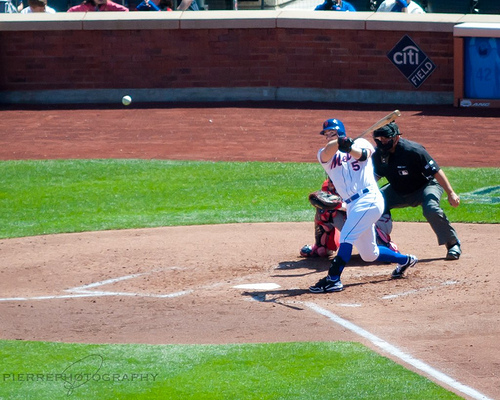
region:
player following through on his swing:
[293, 103, 422, 294]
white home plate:
[240, 280, 276, 293]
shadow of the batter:
[237, 280, 308, 313]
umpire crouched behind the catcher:
[370, 127, 465, 257]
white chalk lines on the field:
[2, 252, 482, 399]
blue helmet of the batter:
[315, 114, 342, 138]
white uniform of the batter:
[318, 148, 380, 255]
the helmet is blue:
[321, 119, 348, 132]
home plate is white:
[237, 271, 282, 310]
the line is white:
[300, 298, 450, 398]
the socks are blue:
[335, 239, 405, 277]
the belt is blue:
[344, 195, 376, 205]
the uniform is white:
[322, 137, 392, 273]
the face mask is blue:
[377, 127, 397, 156]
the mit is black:
[307, 192, 345, 217]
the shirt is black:
[379, 140, 444, 201]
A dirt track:
[105, 239, 226, 304]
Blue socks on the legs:
[335, 242, 353, 280]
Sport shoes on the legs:
[297, 252, 436, 293]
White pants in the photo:
[347, 190, 382, 252]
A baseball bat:
[360, 102, 401, 144]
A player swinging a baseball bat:
[277, 102, 419, 279]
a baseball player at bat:
[305, 109, 417, 291]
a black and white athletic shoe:
[307, 275, 342, 294]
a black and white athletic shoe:
[390, 252, 417, 277]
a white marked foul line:
[0, 291, 93, 302]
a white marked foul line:
[304, 302, 489, 399]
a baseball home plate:
[232, 280, 279, 290]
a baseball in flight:
[121, 94, 130, 104]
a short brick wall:
[0, 13, 457, 109]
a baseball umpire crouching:
[371, 122, 462, 260]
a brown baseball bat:
[349, 109, 401, 140]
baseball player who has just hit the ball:
[313, 113, 415, 292]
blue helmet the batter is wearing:
[318, 117, 347, 137]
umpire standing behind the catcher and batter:
[368, 122, 462, 265]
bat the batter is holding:
[350, 108, 403, 150]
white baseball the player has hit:
[118, 92, 134, 107]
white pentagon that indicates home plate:
[226, 275, 283, 293]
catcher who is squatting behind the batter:
[295, 173, 392, 263]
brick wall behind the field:
[2, 54, 461, 104]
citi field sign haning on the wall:
[387, 54, 434, 86]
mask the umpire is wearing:
[370, 123, 396, 153]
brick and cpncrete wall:
[1, 11, 450, 107]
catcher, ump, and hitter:
[297, 109, 462, 294]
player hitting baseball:
[308, 108, 418, 293]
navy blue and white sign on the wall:
[391, 34, 434, 85]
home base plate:
[231, 277, 283, 297]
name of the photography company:
[2, 367, 172, 391]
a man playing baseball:
[313, 105, 405, 261]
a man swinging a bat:
[328, 101, 415, 233]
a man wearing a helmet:
[313, 110, 347, 162]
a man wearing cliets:
[314, 241, 365, 313]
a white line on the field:
[297, 276, 464, 395]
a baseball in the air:
[113, 93, 141, 113]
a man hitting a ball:
[306, 94, 437, 288]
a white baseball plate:
[235, 266, 305, 322]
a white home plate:
[226, 264, 278, 301]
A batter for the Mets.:
[311, 106, 417, 293]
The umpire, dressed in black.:
[366, 116, 464, 261]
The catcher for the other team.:
[300, 179, 395, 264]